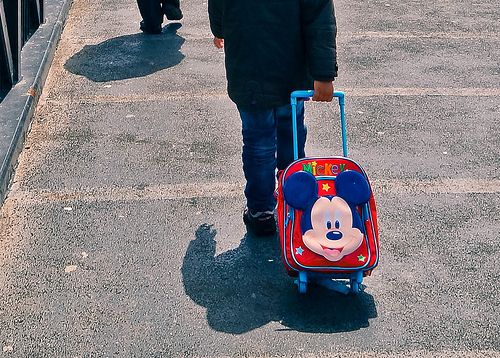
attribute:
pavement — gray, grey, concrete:
[0, 0, 500, 357]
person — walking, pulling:
[207, 1, 338, 238]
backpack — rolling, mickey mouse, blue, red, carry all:
[273, 91, 380, 295]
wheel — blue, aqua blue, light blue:
[293, 270, 308, 292]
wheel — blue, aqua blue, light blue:
[349, 270, 366, 293]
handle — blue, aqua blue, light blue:
[290, 89, 349, 161]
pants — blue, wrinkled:
[236, 102, 306, 210]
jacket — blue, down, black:
[208, 0, 339, 111]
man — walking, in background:
[136, 0, 183, 34]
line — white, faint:
[60, 29, 499, 42]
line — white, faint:
[38, 87, 499, 104]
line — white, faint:
[3, 179, 500, 205]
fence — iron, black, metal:
[1, 0, 45, 102]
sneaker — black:
[243, 202, 277, 237]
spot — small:
[105, 84, 112, 90]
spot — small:
[124, 113, 136, 119]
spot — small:
[64, 205, 72, 211]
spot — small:
[82, 251, 88, 258]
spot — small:
[64, 264, 79, 275]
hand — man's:
[312, 80, 334, 101]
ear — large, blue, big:
[282, 170, 318, 210]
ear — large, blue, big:
[335, 169, 370, 205]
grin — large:
[319, 244, 345, 259]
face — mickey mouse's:
[302, 195, 365, 262]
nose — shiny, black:
[325, 230, 343, 241]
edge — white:
[248, 210, 275, 218]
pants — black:
[136, 0, 181, 25]